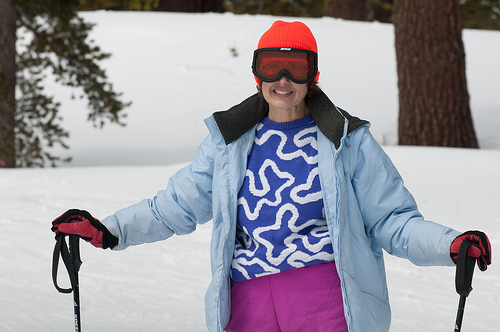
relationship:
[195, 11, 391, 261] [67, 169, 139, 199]
woman in snow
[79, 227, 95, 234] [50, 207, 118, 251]
pink black glove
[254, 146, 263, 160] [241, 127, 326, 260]
purple white shirt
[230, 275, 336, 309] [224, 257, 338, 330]
top of pants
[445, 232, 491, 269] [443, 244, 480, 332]
hand holding pole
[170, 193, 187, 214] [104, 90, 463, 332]
blue snow coat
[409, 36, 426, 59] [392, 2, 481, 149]
brown tree trunk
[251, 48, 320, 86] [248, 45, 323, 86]
goggles with goggles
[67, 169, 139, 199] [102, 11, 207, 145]
snow on ground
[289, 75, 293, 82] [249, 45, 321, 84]
black protective eye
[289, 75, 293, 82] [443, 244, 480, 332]
black ski pole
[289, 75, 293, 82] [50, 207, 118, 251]
black red glove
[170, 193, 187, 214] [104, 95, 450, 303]
blue winter coat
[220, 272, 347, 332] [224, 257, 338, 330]
pair of pants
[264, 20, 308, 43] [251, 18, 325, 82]
orange stocking cap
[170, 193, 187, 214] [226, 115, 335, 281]
blue white shirt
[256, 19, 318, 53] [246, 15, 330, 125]
hat on head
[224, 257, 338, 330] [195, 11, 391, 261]
pants on woman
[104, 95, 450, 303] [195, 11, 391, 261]
coat on woman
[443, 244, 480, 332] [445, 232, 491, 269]
pole in hand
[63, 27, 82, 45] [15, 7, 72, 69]
leaf covered limb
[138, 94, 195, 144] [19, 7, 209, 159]
snowy white slope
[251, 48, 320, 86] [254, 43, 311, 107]
goggles on face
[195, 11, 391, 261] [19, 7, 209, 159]
woman on slope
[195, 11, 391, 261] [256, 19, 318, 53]
woman wearing hat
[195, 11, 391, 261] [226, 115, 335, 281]
woman wearing shirt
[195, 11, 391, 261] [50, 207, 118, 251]
woman wearing glove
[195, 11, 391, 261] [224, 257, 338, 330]
woman wearing pants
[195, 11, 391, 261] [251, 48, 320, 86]
woman wearing goggles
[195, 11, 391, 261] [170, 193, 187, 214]
woman wearing blue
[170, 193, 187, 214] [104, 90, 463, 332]
blue ski coat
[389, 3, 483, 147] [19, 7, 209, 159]
tree in slope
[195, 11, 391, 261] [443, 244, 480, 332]
woman holding pole